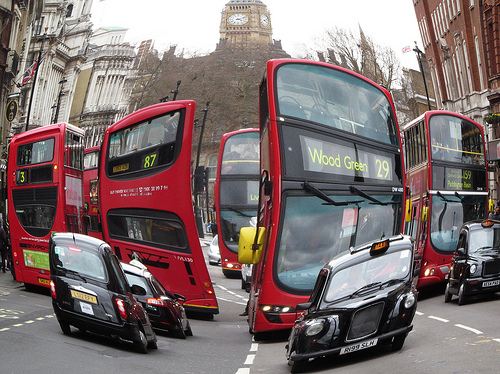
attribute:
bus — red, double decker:
[220, 133, 258, 267]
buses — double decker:
[247, 47, 423, 322]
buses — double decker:
[398, 105, 497, 286]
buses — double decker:
[210, 114, 273, 287]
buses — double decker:
[99, 107, 221, 309]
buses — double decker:
[2, 120, 89, 306]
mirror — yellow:
[237, 225, 265, 262]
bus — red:
[247, 56, 412, 333]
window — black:
[324, 245, 412, 301]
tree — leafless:
[131, 42, 408, 147]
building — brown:
[138, 2, 387, 241]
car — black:
[282, 233, 417, 373]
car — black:
[47, 226, 159, 353]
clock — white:
[226, 9, 272, 31]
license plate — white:
[337, 337, 380, 354]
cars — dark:
[33, 206, 220, 352]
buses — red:
[6, 52, 498, 359]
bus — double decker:
[248, 45, 408, 352]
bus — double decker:
[94, 94, 221, 319]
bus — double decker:
[4, 113, 89, 297]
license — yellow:
[325, 315, 396, 367]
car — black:
[232, 202, 436, 372]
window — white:
[453, 35, 473, 95]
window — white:
[438, 56, 456, 103]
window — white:
[422, 58, 447, 108]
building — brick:
[406, 0, 496, 170]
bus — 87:
[249, 47, 423, 347]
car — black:
[38, 223, 159, 357]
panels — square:
[213, 1, 284, 38]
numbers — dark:
[229, 11, 246, 26]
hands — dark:
[258, 11, 268, 28]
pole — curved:
[193, 86, 225, 265]